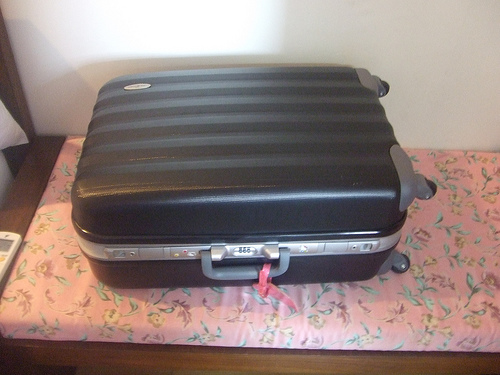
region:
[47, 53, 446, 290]
the suitcase is black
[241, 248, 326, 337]
the ribbon is red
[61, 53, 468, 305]
A piece of luggage on a cushion.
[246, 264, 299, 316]
A pink ribbon on the handle.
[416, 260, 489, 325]
A floral design against a pink background.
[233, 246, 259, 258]
The combination lock on the luggage.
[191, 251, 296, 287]
The handle of the luggage.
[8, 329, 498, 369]
The wooden frame of the furniture.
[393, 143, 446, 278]
The wheels of the luggage.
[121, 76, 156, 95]
An oval sticker at the upper left corner.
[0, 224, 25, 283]
A device on the table.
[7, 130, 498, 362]
This is a pink cushion.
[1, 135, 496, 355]
pink and gray mat on a wooden table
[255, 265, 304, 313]
pink ribbon on a gray suitcase handle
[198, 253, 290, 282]
light gray handle on a dark gray suitcase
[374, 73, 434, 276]
wheels on a dark gray suitcase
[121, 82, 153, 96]
silver oval logo on a dark gray suitcase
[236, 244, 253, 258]
combination locks on a dark gray suitcase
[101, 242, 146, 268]
latch on a dark gray suitcase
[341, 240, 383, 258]
latch on a dark gray suitcase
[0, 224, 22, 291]
remote control on a dark wood table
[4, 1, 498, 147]
white wall behind a dark gray suitcase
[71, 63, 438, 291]
Piece of hard shell luggage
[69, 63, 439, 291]
Black luggage with wheels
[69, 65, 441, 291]
Black and silver locking case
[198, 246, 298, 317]
Luggage handle with pink ribbon attached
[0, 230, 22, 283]
White old-fashioned cell phone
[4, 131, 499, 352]
Cushion with pink cover decorated with multicolored flowers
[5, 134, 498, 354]
Small floral print design on pink fabric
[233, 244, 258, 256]
Combination lock on black case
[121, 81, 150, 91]
Silver disk attached to case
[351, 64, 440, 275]
Wheels and brackets attached to black luggage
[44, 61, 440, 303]
the suitcase is closed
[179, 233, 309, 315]
the handle is gray